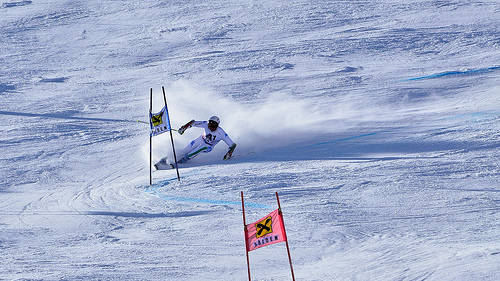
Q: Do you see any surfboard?
A: No, there are no surfboards.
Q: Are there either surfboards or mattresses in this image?
A: No, there are no surfboards or mattresses.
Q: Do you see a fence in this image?
A: No, there are no fences.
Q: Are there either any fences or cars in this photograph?
A: No, there are no fences or cars.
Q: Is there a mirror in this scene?
A: No, there are no mirrors.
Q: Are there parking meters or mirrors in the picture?
A: No, there are no mirrors or parking meters.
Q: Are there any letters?
A: Yes, there are letters.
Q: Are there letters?
A: Yes, there are letters.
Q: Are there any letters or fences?
A: Yes, there are letters.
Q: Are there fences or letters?
A: Yes, there are letters.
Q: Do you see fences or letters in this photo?
A: Yes, there are letters.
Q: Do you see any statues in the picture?
A: No, there are no statues.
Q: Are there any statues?
A: No, there are no statues.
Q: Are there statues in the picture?
A: No, there are no statues.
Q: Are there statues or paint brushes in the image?
A: No, there are no statues or paint brushes.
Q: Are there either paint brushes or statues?
A: No, there are no statues or paint brushes.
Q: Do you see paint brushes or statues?
A: No, there are no statues or paint brushes.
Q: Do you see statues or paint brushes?
A: No, there are no statues or paint brushes.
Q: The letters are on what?
A: The letters are on the sign.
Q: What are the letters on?
A: The letters are on the sign.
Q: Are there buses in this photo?
A: No, there are no buses.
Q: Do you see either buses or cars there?
A: No, there are no buses or cars.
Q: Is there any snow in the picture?
A: Yes, there is snow.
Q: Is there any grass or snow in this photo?
A: Yes, there is snow.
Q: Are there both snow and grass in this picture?
A: No, there is snow but no grass.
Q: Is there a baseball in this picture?
A: No, there are no baseballs.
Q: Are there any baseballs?
A: No, there are no baseballs.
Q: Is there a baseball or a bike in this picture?
A: No, there are no baseballs or bikes.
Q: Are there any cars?
A: No, there are no cars.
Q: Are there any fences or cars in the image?
A: No, there are no cars or fences.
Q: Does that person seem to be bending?
A: Yes, the person is bending.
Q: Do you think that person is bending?
A: Yes, the person is bending.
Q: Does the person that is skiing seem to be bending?
A: Yes, the person is bending.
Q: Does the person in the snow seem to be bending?
A: Yes, the person is bending.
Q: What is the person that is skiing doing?
A: The person is bending.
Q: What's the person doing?
A: The person is bending.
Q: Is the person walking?
A: No, the person is bending.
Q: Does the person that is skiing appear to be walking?
A: No, the person is bending.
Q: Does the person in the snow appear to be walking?
A: No, the person is bending.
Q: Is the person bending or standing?
A: The person is bending.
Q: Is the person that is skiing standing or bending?
A: The person is bending.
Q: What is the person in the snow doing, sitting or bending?
A: The person is bending.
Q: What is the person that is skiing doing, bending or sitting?
A: The person is bending.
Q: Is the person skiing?
A: Yes, the person is skiing.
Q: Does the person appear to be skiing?
A: Yes, the person is skiing.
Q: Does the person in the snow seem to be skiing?
A: Yes, the person is skiing.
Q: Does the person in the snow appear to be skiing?
A: Yes, the person is skiing.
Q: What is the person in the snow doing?
A: The person is skiing.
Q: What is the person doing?
A: The person is skiing.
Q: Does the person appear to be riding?
A: No, the person is skiing.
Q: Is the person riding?
A: No, the person is skiing.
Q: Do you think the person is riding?
A: No, the person is skiing.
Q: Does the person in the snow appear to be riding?
A: No, the person is skiing.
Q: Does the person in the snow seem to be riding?
A: No, the person is skiing.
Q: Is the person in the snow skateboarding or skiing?
A: The person is skiing.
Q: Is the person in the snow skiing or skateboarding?
A: The person is skiing.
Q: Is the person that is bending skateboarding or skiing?
A: The person is skiing.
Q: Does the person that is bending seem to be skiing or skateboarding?
A: The person is skiing.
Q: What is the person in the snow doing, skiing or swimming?
A: The person is skiing.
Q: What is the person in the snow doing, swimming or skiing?
A: The person is skiing.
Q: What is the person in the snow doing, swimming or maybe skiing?
A: The person is skiing.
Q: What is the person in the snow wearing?
A: The person is wearing a helmet.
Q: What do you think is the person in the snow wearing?
A: The person is wearing a helmet.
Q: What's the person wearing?
A: The person is wearing a helmet.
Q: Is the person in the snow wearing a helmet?
A: Yes, the person is wearing a helmet.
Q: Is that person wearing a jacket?
A: No, the person is wearing a helmet.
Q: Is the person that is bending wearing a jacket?
A: No, the person is wearing a helmet.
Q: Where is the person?
A: The person is in the snow.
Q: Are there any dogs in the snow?
A: No, there is a person in the snow.